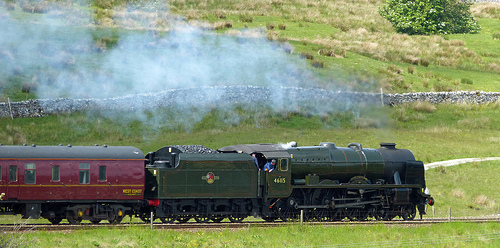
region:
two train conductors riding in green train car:
[250, 149, 278, 173]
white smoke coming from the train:
[107, 30, 295, 108]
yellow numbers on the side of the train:
[270, 174, 289, 187]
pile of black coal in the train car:
[172, 142, 215, 156]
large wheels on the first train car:
[278, 179, 390, 218]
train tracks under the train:
[35, 220, 466, 229]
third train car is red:
[1, 139, 144, 202]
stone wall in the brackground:
[41, 84, 493, 108]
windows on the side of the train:
[22, 159, 112, 187]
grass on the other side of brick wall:
[273, 7, 368, 87]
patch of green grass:
[469, 135, 490, 150]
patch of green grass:
[419, 232, 431, 242]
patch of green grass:
[333, 228, 351, 240]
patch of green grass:
[309, 228, 334, 245]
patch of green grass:
[278, 225, 299, 245]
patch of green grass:
[263, 228, 282, 243]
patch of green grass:
[456, 165, 473, 184]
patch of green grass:
[419, 129, 437, 139]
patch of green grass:
[427, 120, 443, 137]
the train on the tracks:
[4, 133, 426, 220]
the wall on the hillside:
[5, 78, 498, 116]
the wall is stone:
[3, 90, 498, 119]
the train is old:
[6, 130, 437, 222]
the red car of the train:
[5, 135, 147, 215]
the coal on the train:
[152, 133, 265, 212]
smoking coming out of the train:
[28, 23, 374, 139]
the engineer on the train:
[260, 151, 275, 171]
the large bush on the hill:
[384, 2, 494, 33]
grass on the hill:
[29, 8, 498, 77]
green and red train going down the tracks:
[10, 127, 449, 227]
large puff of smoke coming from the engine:
[26, 22, 368, 127]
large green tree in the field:
[374, 0, 481, 40]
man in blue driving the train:
[262, 158, 284, 170]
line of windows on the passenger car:
[3, 158, 115, 189]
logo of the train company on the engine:
[196, 170, 221, 186]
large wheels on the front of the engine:
[298, 185, 410, 222]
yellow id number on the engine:
[272, 172, 289, 186]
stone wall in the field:
[362, 79, 497, 114]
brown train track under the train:
[78, 220, 323, 232]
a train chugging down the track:
[2, 140, 436, 222]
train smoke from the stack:
[2, 3, 396, 141]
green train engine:
[260, 147, 436, 219]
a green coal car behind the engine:
[147, 143, 259, 223]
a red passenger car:
[1, 146, 143, 227]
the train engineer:
[260, 159, 277, 171]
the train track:
[2, 216, 499, 229]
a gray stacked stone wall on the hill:
[3, 87, 498, 116]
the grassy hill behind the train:
[5, 0, 496, 152]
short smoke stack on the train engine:
[380, 140, 398, 147]